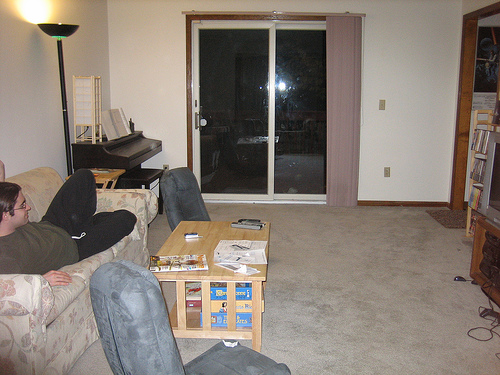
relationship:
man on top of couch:
[2, 172, 138, 270] [0, 166, 154, 374]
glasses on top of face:
[12, 201, 30, 209] [14, 195, 29, 226]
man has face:
[2, 172, 138, 270] [14, 195, 29, 226]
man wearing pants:
[2, 172, 138, 270] [44, 170, 136, 257]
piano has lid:
[74, 128, 165, 185] [103, 134, 159, 158]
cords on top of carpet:
[463, 293, 498, 343] [77, 193, 500, 368]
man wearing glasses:
[2, 172, 138, 270] [12, 201, 30, 209]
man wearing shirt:
[2, 172, 138, 270] [6, 224, 77, 275]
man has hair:
[2, 172, 138, 270] [2, 183, 17, 214]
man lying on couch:
[2, 172, 138, 270] [0, 166, 154, 374]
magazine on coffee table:
[151, 253, 205, 272] [152, 218, 271, 335]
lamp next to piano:
[41, 22, 78, 176] [74, 128, 165, 185]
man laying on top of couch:
[2, 172, 138, 270] [0, 166, 154, 374]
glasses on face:
[12, 201, 30, 209] [14, 195, 29, 226]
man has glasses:
[2, 172, 138, 270] [12, 201, 30, 209]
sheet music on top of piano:
[99, 108, 127, 139] [74, 128, 165, 185]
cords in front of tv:
[463, 293, 498, 343] [476, 127, 500, 218]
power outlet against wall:
[380, 99, 387, 113] [107, 3, 461, 204]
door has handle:
[191, 21, 326, 195] [194, 112, 199, 129]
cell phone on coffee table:
[184, 233, 197, 239] [152, 218, 271, 335]